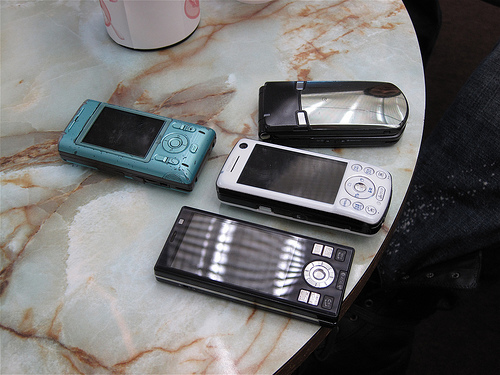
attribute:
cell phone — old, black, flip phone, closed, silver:
[256, 78, 410, 149]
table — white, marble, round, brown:
[1, 3, 429, 374]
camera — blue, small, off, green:
[54, 97, 218, 193]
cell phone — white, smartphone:
[212, 134, 393, 240]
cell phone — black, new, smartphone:
[151, 205, 355, 331]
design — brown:
[3, 8, 408, 344]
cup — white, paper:
[94, 1, 204, 52]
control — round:
[342, 172, 376, 200]